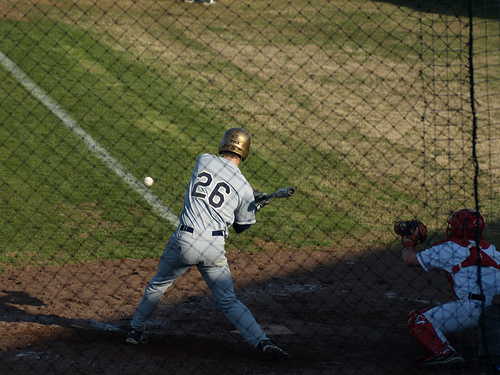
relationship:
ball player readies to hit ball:
[125, 127, 292, 364] [137, 171, 159, 189]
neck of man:
[147, 107, 289, 354] [215, 122, 255, 172]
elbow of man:
[228, 215, 258, 243] [112, 110, 312, 362]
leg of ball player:
[204, 261, 266, 348] [125, 127, 292, 364]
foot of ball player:
[64, 307, 200, 373] [125, 127, 292, 364]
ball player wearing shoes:
[125, 127, 292, 364] [122, 326, 154, 343]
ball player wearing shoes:
[125, 127, 292, 364] [251, 332, 296, 359]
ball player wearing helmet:
[125, 127, 292, 364] [217, 125, 250, 157]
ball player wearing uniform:
[125, 127, 292, 364] [127, 151, 268, 334]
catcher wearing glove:
[392, 208, 499, 368] [389, 214, 428, 241]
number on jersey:
[191, 171, 231, 209] [181, 150, 257, 230]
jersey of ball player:
[181, 150, 257, 230] [129, 129, 290, 364]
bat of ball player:
[253, 184, 297, 200] [125, 127, 292, 364]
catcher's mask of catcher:
[443, 206, 486, 239] [392, 211, 496, 372]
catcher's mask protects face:
[443, 206, 486, 239] [445, 219, 454, 240]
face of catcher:
[445, 219, 454, 240] [392, 211, 496, 372]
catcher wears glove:
[392, 208, 499, 368] [395, 209, 431, 242]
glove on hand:
[395, 209, 431, 242] [402, 226, 420, 246]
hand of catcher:
[402, 226, 420, 246] [392, 208, 499, 368]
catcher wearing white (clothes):
[392, 208, 499, 368] [418, 238, 494, 349]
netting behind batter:
[2, 1, 498, 372] [111, 135, 288, 367]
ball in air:
[133, 168, 158, 195] [10, 7, 485, 237]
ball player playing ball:
[125, 127, 292, 364] [143, 176, 155, 187]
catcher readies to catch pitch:
[392, 211, 496, 372] [144, 171, 155, 185]